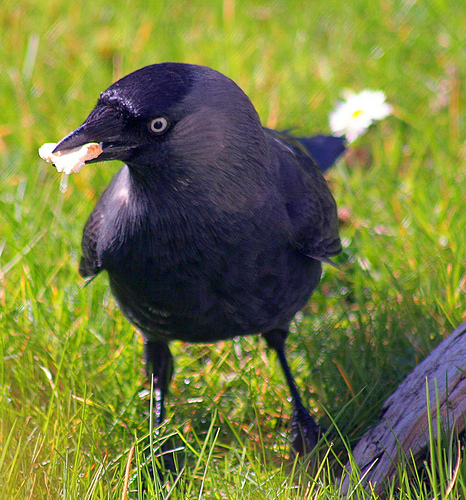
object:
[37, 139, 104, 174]
bread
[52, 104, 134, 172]
beak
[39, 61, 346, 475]
bird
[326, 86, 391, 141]
flower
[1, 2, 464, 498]
grass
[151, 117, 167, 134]
eye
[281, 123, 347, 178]
tailfeathers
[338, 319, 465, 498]
branch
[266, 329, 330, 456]
feet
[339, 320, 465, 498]
log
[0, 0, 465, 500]
field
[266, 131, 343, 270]
wing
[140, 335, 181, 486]
leg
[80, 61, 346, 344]
black feathers